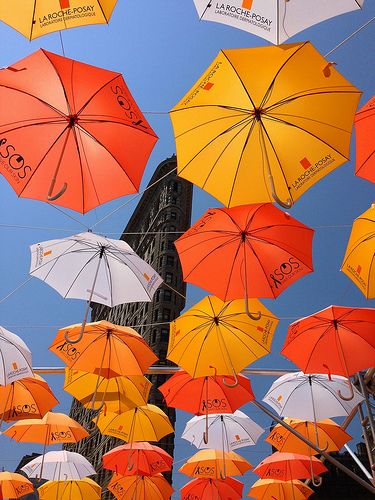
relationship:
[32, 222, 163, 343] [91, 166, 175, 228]
umbrella on wire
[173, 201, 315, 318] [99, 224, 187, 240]
umbrella on wire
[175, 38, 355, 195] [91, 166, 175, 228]
umbrella on wire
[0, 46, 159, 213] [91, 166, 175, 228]
umbrella on wire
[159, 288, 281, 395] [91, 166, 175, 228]
umbrella on wire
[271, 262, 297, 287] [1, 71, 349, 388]
awareness on umbrella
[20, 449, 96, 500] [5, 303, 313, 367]
umbrella on wire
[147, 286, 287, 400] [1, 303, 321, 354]
umbrella on wire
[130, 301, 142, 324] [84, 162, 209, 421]
window on building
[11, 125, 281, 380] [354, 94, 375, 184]
cables holding umbrella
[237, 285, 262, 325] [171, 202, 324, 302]
handle hanging from umbrella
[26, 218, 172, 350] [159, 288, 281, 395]
umbrella next to umbrella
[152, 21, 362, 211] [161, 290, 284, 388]
umbrella next to umbrella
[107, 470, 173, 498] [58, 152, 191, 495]
umbrella near building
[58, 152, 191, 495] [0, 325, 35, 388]
building behind umbrella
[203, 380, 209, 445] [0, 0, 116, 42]
bars along umbrella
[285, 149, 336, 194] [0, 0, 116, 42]
logo on umbrella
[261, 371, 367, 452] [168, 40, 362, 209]
umbrella by umbrella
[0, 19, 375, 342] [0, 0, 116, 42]
wires on umbrella